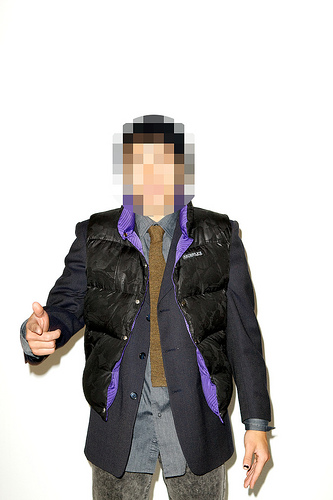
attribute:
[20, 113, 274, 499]
man — standing, pointing, photo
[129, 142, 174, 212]
face — censored, blurred, pixellated, digital, pixels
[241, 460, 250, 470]
nailpolish — black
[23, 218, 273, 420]
shirt — long sleeved, grey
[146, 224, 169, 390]
tie — brown, long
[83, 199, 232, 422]
vest — black, purple, quilted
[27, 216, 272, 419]
jacket — dark grey, grey, black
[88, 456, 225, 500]
jean — black, stone wash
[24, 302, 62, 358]
hand — pointing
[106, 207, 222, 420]
lining — purple, blue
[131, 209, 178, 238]
collar — grey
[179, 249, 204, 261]
letters — white